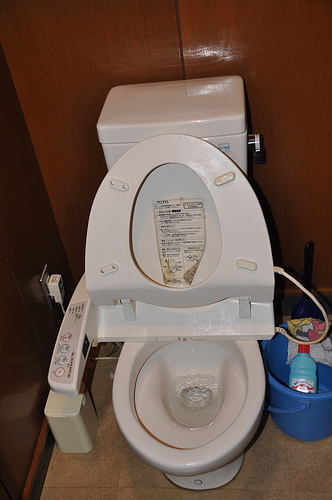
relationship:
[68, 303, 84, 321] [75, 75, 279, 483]
black writing in toilet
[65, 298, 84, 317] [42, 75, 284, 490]
writing in toilet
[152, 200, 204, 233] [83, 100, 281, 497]
writing in toilet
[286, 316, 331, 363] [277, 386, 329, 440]
rag over bucket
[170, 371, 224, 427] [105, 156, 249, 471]
water in toilet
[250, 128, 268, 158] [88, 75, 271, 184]
knob on tank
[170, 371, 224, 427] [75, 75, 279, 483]
water in toilet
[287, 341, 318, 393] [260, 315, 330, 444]
bottle in bucket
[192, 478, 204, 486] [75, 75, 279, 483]
button on toilet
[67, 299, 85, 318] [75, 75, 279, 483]
writing on toilet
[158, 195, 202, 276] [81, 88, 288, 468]
writing on toilet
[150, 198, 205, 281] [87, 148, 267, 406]
writing on toilet